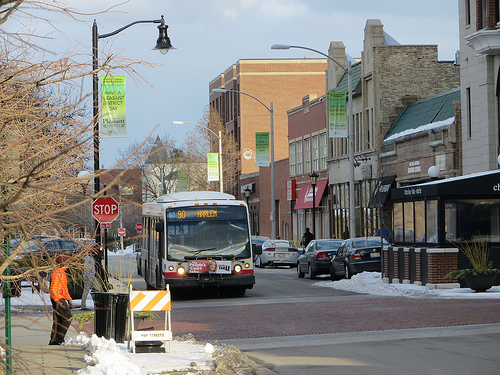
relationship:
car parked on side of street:
[243, 232, 304, 286] [238, 254, 373, 346]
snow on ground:
[324, 258, 452, 337] [122, 222, 443, 357]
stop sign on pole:
[87, 191, 122, 226] [102, 229, 112, 290]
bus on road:
[141, 191, 256, 296] [127, 289, 498, 366]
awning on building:
[295, 182, 329, 210] [280, 93, 330, 245]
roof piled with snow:
[387, 86, 456, 146] [379, 111, 459, 141]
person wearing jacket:
[48, 255, 74, 345] [51, 264, 73, 302]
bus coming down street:
[142, 192, 264, 304] [178, 294, 498, 372]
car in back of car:
[332, 235, 386, 282] [295, 236, 344, 279]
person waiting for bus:
[43, 247, 79, 343] [139, 191, 259, 297]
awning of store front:
[294, 179, 329, 210] [280, 105, 339, 250]